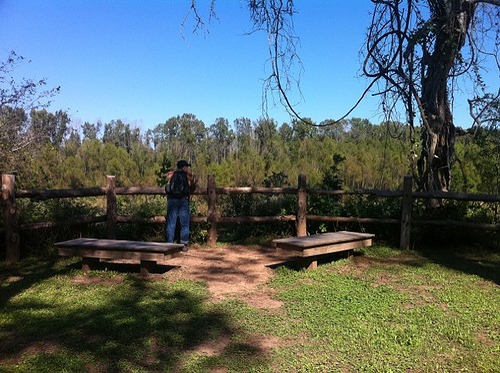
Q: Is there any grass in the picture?
A: Yes, there is grass.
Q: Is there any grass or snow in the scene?
A: Yes, there is grass.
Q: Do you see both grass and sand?
A: No, there is grass but no sand.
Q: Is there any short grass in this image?
A: Yes, there is short grass.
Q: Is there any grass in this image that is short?
A: Yes, there is grass that is short.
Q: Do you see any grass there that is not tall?
A: Yes, there is short grass.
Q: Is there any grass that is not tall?
A: Yes, there is short grass.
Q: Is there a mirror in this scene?
A: No, there are no mirrors.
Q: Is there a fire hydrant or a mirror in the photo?
A: No, there are no mirrors or fire hydrants.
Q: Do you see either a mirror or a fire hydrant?
A: No, there are no mirrors or fire hydrants.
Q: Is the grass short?
A: Yes, the grass is short.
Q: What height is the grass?
A: The grass is short.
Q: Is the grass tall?
A: No, the grass is short.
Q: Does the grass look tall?
A: No, the grass is short.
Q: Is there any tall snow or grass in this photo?
A: No, there is grass but it is short.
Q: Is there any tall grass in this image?
A: No, there is grass but it is short.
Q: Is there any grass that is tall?
A: No, there is grass but it is short.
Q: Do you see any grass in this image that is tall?
A: No, there is grass but it is short.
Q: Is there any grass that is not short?
A: No, there is grass but it is short.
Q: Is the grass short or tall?
A: The grass is short.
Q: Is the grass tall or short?
A: The grass is short.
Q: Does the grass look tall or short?
A: The grass is short.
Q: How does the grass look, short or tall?
A: The grass is short.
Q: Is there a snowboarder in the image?
A: No, there are no snowboarders.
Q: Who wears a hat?
A: The man wears a hat.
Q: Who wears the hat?
A: The man wears a hat.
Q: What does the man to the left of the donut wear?
A: The man wears a hat.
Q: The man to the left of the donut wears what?
A: The man wears a hat.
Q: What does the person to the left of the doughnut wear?
A: The man wears a hat.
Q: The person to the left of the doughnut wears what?
A: The man wears a hat.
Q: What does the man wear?
A: The man wears a hat.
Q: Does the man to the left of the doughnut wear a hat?
A: Yes, the man wears a hat.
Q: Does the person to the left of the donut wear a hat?
A: Yes, the man wears a hat.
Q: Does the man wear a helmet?
A: No, the man wears a hat.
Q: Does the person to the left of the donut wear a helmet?
A: No, the man wears a hat.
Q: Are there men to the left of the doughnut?
A: Yes, there is a man to the left of the doughnut.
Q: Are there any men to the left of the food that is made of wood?
A: Yes, there is a man to the left of the doughnut.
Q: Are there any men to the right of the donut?
A: No, the man is to the left of the donut.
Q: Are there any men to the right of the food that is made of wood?
A: No, the man is to the left of the donut.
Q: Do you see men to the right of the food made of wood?
A: No, the man is to the left of the donut.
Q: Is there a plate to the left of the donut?
A: No, there is a man to the left of the donut.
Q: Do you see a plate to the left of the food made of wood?
A: No, there is a man to the left of the donut.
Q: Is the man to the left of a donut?
A: Yes, the man is to the left of a donut.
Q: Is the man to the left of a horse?
A: No, the man is to the left of a donut.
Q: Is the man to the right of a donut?
A: No, the man is to the left of a donut.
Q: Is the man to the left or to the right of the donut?
A: The man is to the left of the donut.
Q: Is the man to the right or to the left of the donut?
A: The man is to the left of the donut.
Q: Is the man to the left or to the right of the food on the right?
A: The man is to the left of the donut.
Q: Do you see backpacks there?
A: Yes, there is a backpack.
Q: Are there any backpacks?
A: Yes, there is a backpack.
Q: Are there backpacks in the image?
A: Yes, there is a backpack.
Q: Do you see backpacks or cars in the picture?
A: Yes, there is a backpack.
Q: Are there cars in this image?
A: No, there are no cars.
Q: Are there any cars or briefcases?
A: No, there are no cars or briefcases.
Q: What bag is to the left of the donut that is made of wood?
A: The bag is a backpack.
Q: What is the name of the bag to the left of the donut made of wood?
A: The bag is a backpack.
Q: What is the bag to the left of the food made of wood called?
A: The bag is a backpack.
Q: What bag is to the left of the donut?
A: The bag is a backpack.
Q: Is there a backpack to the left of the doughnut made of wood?
A: Yes, there is a backpack to the left of the donut.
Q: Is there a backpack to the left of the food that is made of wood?
A: Yes, there is a backpack to the left of the donut.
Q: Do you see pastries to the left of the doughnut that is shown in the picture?
A: No, there is a backpack to the left of the doughnut.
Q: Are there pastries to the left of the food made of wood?
A: No, there is a backpack to the left of the doughnut.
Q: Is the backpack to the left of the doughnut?
A: Yes, the backpack is to the left of the doughnut.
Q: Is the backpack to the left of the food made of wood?
A: Yes, the backpack is to the left of the doughnut.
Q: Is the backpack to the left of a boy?
A: No, the backpack is to the left of the doughnut.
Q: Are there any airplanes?
A: No, there are no airplanes.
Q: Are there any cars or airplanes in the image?
A: No, there are no airplanes or cars.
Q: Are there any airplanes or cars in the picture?
A: No, there are no airplanes or cars.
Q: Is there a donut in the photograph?
A: Yes, there is a donut.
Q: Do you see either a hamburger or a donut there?
A: Yes, there is a donut.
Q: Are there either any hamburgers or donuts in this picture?
A: Yes, there is a donut.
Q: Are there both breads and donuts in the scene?
A: No, there is a donut but no breads.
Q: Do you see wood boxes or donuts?
A: Yes, there is a wood donut.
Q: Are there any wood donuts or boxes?
A: Yes, there is a wood donut.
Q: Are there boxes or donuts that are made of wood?
A: Yes, the donut is made of wood.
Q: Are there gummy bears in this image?
A: No, there are no gummy bears.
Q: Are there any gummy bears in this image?
A: No, there are no gummy bears.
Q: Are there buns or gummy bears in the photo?
A: No, there are no gummy bears or buns.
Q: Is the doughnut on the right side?
A: Yes, the doughnut is on the right of the image.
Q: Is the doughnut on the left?
A: No, the doughnut is on the right of the image.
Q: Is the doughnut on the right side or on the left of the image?
A: The doughnut is on the right of the image.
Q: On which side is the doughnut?
A: The doughnut is on the right of the image.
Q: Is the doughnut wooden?
A: Yes, the doughnut is wooden.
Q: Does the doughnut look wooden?
A: Yes, the doughnut is wooden.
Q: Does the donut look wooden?
A: Yes, the donut is wooden.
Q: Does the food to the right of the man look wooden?
A: Yes, the donut is wooden.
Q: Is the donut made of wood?
A: Yes, the donut is made of wood.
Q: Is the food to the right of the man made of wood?
A: Yes, the donut is made of wood.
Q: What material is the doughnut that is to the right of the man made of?
A: The donut is made of wood.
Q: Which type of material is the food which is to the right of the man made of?
A: The donut is made of wood.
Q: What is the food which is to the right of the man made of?
A: The donut is made of wood.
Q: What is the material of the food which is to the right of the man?
A: The donut is made of wood.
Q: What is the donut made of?
A: The donut is made of wood.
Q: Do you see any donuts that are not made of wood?
A: No, there is a donut but it is made of wood.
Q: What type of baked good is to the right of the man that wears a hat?
A: The food is a donut.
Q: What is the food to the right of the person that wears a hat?
A: The food is a donut.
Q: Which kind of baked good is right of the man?
A: The food is a donut.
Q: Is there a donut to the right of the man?
A: Yes, there is a donut to the right of the man.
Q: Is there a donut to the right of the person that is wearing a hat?
A: Yes, there is a donut to the right of the man.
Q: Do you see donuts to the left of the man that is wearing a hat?
A: No, the donut is to the right of the man.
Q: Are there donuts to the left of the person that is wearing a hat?
A: No, the donut is to the right of the man.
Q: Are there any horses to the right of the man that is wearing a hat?
A: No, there is a donut to the right of the man.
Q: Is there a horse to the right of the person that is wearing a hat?
A: No, there is a donut to the right of the man.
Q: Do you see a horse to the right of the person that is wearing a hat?
A: No, there is a donut to the right of the man.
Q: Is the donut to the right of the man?
A: Yes, the donut is to the right of the man.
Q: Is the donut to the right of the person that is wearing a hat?
A: Yes, the donut is to the right of the man.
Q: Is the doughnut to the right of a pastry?
A: No, the doughnut is to the right of the man.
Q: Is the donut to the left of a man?
A: No, the donut is to the right of a man.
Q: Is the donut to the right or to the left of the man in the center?
A: The donut is to the right of the man.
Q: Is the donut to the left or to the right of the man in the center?
A: The donut is to the right of the man.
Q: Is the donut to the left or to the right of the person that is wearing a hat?
A: The donut is to the right of the man.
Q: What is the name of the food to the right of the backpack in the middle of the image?
A: The food is a donut.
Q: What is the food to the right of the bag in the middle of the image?
A: The food is a donut.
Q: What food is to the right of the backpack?
A: The food is a donut.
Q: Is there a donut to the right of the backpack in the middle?
A: Yes, there is a donut to the right of the backpack.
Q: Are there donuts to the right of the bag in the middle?
A: Yes, there is a donut to the right of the backpack.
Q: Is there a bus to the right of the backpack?
A: No, there is a donut to the right of the backpack.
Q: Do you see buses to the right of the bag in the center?
A: No, there is a donut to the right of the backpack.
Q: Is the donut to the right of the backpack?
A: Yes, the donut is to the right of the backpack.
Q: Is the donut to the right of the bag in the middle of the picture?
A: Yes, the donut is to the right of the backpack.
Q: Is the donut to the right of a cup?
A: No, the donut is to the right of the backpack.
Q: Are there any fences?
A: Yes, there is a fence.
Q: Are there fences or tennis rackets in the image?
A: Yes, there is a fence.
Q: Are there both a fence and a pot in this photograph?
A: No, there is a fence but no pots.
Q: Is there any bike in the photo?
A: No, there are no bikes.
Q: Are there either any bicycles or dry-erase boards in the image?
A: No, there are no bicycles or dry-erase boards.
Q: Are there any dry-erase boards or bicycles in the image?
A: No, there are no bicycles or dry-erase boards.